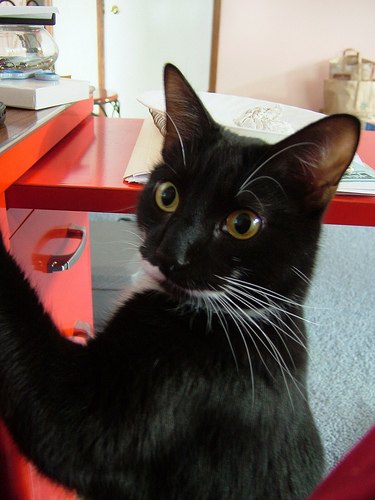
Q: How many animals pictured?
A: One.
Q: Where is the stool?
A: Front of door.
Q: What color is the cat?
A: Black and white.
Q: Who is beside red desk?
A: Cat.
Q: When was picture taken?
A: Daytime.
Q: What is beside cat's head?
A: Papers.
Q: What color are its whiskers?
A: White.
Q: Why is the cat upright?
A: Climbing.